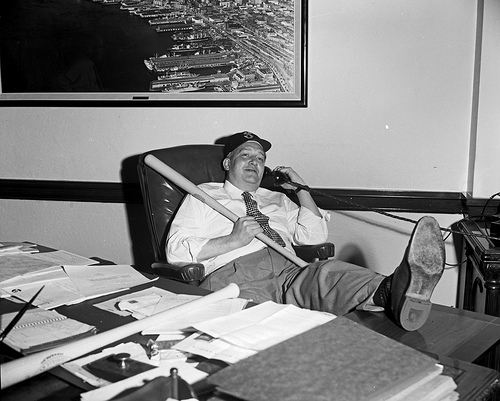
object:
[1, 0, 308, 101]
photo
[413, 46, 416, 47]
wall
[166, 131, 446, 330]
man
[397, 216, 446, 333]
shoe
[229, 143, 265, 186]
face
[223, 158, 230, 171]
ear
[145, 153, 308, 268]
bat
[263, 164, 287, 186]
phone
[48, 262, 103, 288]
papers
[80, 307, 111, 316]
desk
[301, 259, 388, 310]
leg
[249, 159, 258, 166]
nose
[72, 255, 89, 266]
cober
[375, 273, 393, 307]
sock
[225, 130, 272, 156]
hat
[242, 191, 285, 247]
tie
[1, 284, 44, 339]
pen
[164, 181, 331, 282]
shirt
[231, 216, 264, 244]
hand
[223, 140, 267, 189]
head